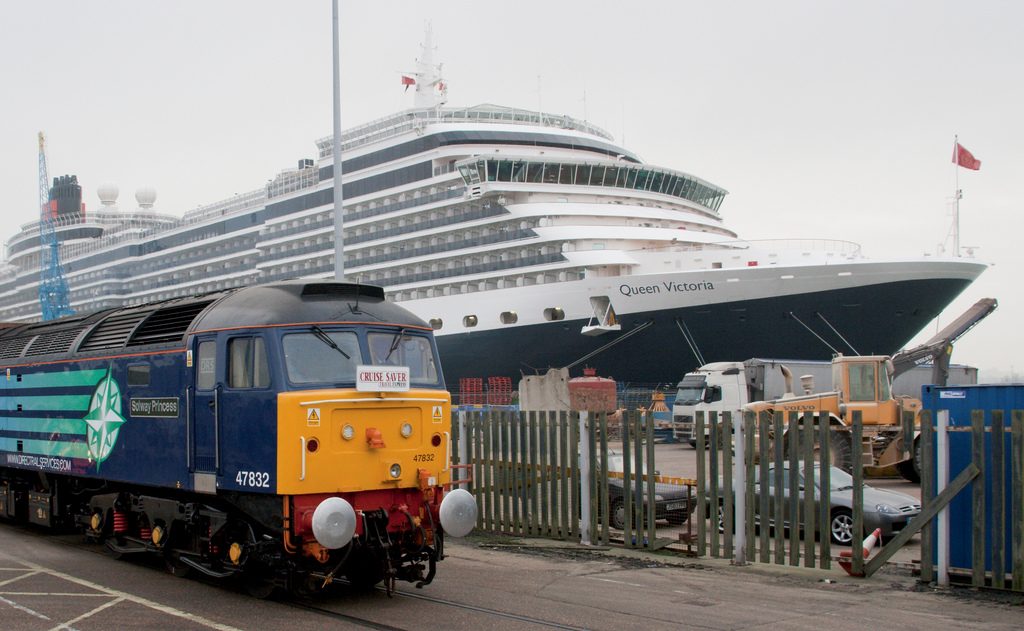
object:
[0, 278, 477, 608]
train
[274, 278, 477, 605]
front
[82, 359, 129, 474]
star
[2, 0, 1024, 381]
sky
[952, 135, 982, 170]
flag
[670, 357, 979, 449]
vehicle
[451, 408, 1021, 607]
fence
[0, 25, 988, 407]
boat